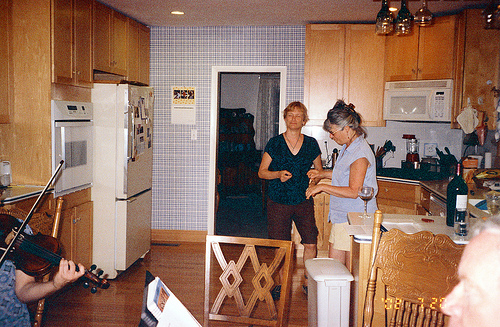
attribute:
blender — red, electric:
[400, 130, 424, 166]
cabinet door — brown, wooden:
[303, 20, 344, 120]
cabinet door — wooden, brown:
[345, 24, 388, 123]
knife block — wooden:
[438, 147, 458, 187]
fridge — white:
[94, 81, 155, 284]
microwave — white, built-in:
[379, 76, 459, 126]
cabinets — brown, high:
[98, 10, 153, 92]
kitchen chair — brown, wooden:
[200, 230, 290, 324]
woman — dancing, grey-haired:
[299, 97, 382, 260]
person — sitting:
[2, 206, 88, 325]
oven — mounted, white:
[50, 97, 90, 193]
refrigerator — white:
[87, 82, 150, 272]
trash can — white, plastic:
[301, 253, 357, 324]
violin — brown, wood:
[0, 215, 110, 295]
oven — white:
[51, 96, 99, 196]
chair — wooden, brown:
[204, 236, 301, 325]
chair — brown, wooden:
[360, 211, 458, 324]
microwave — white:
[385, 78, 455, 127]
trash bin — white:
[302, 254, 351, 324]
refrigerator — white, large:
[92, 83, 153, 279]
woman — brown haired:
[257, 102, 327, 269]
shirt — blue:
[263, 132, 315, 203]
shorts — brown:
[269, 200, 314, 244]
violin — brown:
[3, 216, 113, 302]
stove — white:
[51, 100, 89, 195]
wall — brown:
[8, 4, 152, 286]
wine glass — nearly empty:
[358, 180, 384, 237]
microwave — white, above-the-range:
[382, 79, 458, 119]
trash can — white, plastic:
[303, 245, 375, 325]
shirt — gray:
[333, 148, 373, 218]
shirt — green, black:
[264, 130, 334, 231]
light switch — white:
[186, 125, 201, 145]